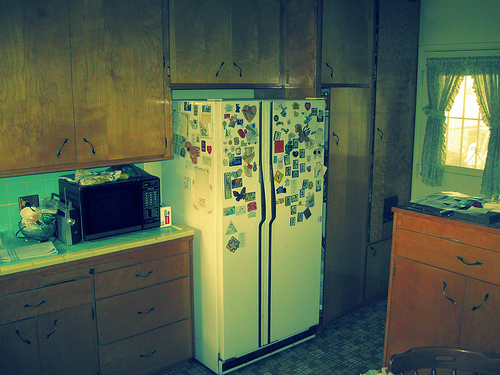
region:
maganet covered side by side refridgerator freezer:
[171, 97, 333, 374]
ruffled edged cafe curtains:
[418, 51, 498, 195]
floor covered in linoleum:
[233, 289, 391, 374]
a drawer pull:
[453, 249, 484, 270]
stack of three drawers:
[95, 247, 197, 373]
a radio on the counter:
[39, 186, 83, 249]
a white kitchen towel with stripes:
[1, 238, 71, 267]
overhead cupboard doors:
[1, 0, 283, 185]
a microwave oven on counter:
[58, 174, 163, 236]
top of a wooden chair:
[375, 336, 494, 373]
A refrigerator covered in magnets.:
[160, 89, 334, 374]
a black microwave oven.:
[52, 154, 173, 257]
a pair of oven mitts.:
[63, 157, 145, 197]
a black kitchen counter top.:
[379, 191, 498, 370]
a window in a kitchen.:
[411, 70, 498, 185]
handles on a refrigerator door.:
[252, 99, 276, 356]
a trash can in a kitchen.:
[371, 335, 498, 374]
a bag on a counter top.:
[12, 198, 60, 265]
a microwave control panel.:
[140, 183, 162, 223]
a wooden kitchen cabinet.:
[67, 0, 182, 167]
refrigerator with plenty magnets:
[161, 93, 327, 371]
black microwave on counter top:
[60, 177, 162, 242]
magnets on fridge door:
[274, 102, 323, 225]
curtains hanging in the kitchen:
[423, 55, 495, 196]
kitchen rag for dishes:
[1, 237, 57, 262]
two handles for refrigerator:
[257, 162, 277, 234]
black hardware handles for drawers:
[134, 272, 158, 359]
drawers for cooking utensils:
[92, 270, 195, 372]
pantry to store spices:
[329, 88, 363, 318]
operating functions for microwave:
[143, 179, 157, 224]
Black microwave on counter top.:
[55, 170, 160, 240]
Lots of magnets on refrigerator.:
[173, 102, 325, 254]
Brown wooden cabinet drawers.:
[0, 260, 202, 372]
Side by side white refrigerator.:
[174, 93, 332, 370]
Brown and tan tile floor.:
[308, 342, 383, 367]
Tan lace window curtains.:
[428, 65, 497, 195]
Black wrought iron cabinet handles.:
[46, 129, 110, 161]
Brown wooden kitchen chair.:
[385, 347, 499, 372]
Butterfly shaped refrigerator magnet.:
[230, 187, 250, 204]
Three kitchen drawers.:
[88, 247, 201, 372]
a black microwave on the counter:
[55, 163, 169, 245]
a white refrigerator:
[168, 80, 336, 373]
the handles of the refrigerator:
[252, 162, 281, 224]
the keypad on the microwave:
[141, 185, 163, 209]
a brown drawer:
[389, 225, 499, 287]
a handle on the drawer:
[449, 252, 487, 269]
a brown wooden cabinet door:
[372, 253, 468, 373]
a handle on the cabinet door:
[433, 275, 456, 310]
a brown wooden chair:
[381, 341, 498, 373]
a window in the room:
[419, 53, 499, 175]